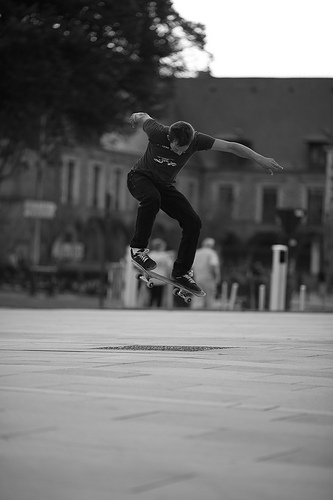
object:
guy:
[129, 112, 283, 294]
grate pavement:
[87, 344, 241, 352]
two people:
[149, 237, 222, 308]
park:
[0, 131, 333, 325]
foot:
[129, 246, 159, 270]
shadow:
[0, 349, 94, 354]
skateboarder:
[94, 343, 237, 352]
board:
[129, 249, 208, 298]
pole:
[31, 218, 41, 266]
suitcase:
[145, 118, 205, 156]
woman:
[147, 238, 172, 307]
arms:
[197, 128, 258, 163]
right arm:
[129, 111, 167, 141]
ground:
[0, 308, 333, 500]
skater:
[126, 112, 284, 294]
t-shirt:
[131, 118, 217, 185]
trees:
[0, 0, 214, 186]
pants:
[127, 172, 202, 276]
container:
[269, 244, 289, 312]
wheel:
[135, 271, 142, 280]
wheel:
[147, 280, 155, 288]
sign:
[22, 198, 57, 221]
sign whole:
[21, 200, 57, 267]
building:
[3, 76, 333, 308]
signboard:
[23, 199, 56, 219]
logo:
[154, 155, 177, 167]